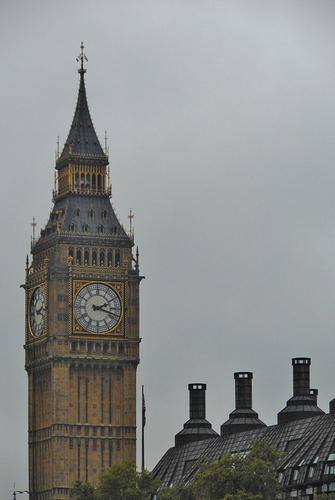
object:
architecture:
[19, 39, 148, 498]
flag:
[140, 382, 146, 471]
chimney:
[291, 355, 311, 399]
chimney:
[233, 369, 254, 409]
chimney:
[186, 381, 208, 421]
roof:
[54, 69, 108, 171]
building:
[148, 355, 335, 499]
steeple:
[55, 37, 110, 197]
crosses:
[126, 206, 136, 233]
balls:
[80, 43, 85, 49]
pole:
[79, 40, 85, 67]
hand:
[91, 302, 120, 318]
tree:
[62, 454, 166, 498]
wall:
[52, 365, 137, 430]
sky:
[0, 0, 335, 499]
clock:
[71, 280, 123, 335]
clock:
[27, 283, 47, 339]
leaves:
[211, 468, 233, 489]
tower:
[18, 38, 148, 498]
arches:
[112, 245, 121, 270]